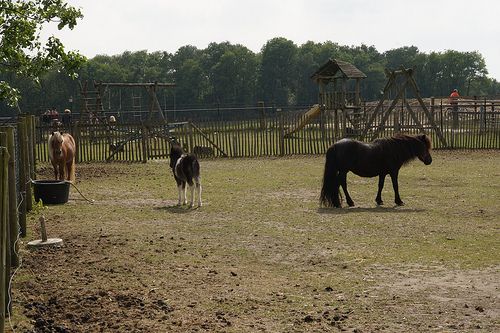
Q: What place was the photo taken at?
A: It was taken at the pasture.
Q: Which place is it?
A: It is a pasture.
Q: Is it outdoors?
A: Yes, it is outdoors.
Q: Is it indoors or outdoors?
A: It is outdoors.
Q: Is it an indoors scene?
A: No, it is outdoors.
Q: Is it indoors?
A: No, it is outdoors.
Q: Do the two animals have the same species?
A: Yes, all the animals are horses.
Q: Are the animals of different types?
A: No, all the animals are horses.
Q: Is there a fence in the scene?
A: Yes, there is a fence.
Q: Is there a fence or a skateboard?
A: Yes, there is a fence.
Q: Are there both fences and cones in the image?
A: No, there is a fence but no cones.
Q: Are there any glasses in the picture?
A: No, there are no glasses.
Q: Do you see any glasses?
A: No, there are no glasses.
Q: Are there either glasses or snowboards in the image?
A: No, there are no glasses or snowboards.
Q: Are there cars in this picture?
A: No, there are no cars.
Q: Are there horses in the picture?
A: Yes, there is a horse.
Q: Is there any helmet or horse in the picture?
A: Yes, there is a horse.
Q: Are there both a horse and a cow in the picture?
A: No, there is a horse but no cows.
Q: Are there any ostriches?
A: No, there are no ostriches.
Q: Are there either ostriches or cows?
A: No, there are no ostriches or cows.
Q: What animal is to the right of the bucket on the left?
A: The animal is a horse.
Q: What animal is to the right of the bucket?
A: The animal is a horse.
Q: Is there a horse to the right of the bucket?
A: Yes, there is a horse to the right of the bucket.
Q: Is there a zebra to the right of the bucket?
A: No, there is a horse to the right of the bucket.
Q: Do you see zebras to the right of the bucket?
A: No, there is a horse to the right of the bucket.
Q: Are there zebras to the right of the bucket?
A: No, there is a horse to the right of the bucket.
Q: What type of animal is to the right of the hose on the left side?
A: The animal is a horse.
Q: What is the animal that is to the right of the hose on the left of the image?
A: The animal is a horse.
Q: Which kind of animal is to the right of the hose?
A: The animal is a horse.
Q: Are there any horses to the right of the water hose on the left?
A: Yes, there is a horse to the right of the water hose.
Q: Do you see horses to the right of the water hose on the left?
A: Yes, there is a horse to the right of the water hose.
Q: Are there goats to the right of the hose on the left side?
A: No, there is a horse to the right of the water hose.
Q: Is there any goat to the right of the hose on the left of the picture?
A: No, there is a horse to the right of the water hose.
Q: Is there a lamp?
A: No, there are no lamps.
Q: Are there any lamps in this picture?
A: No, there are no lamps.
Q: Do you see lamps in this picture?
A: No, there are no lamps.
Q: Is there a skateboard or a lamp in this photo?
A: No, there are no lamps or skateboards.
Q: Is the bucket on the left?
A: Yes, the bucket is on the left of the image.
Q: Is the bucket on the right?
A: No, the bucket is on the left of the image.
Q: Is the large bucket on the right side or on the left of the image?
A: The bucket is on the left of the image.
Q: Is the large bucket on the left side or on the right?
A: The bucket is on the left of the image.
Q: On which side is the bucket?
A: The bucket is on the left of the image.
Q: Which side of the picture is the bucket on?
A: The bucket is on the left of the image.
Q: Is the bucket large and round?
A: Yes, the bucket is large and round.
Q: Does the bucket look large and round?
A: Yes, the bucket is large and round.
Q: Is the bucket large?
A: Yes, the bucket is large.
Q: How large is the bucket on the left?
A: The bucket is large.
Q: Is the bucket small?
A: No, the bucket is large.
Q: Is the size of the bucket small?
A: No, the bucket is large.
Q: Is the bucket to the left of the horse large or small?
A: The bucket is large.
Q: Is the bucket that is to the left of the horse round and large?
A: Yes, the bucket is round and large.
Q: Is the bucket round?
A: Yes, the bucket is round.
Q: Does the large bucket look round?
A: Yes, the bucket is round.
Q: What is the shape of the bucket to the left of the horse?
A: The bucket is round.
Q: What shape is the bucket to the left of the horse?
A: The bucket is round.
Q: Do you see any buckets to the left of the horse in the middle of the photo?
A: Yes, there is a bucket to the left of the horse.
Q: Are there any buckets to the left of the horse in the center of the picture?
A: Yes, there is a bucket to the left of the horse.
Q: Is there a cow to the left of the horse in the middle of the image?
A: No, there is a bucket to the left of the horse.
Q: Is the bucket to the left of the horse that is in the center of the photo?
A: Yes, the bucket is to the left of the horse.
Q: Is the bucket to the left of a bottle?
A: No, the bucket is to the left of the horse.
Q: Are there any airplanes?
A: No, there are no airplanes.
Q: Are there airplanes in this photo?
A: No, there are no airplanes.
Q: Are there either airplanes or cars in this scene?
A: No, there are no airplanes or cars.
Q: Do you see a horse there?
A: Yes, there is a horse.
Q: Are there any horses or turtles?
A: Yes, there is a horse.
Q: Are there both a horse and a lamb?
A: No, there is a horse but no lambs.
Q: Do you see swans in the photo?
A: No, there are no swans.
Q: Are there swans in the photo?
A: No, there are no swans.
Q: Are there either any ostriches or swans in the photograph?
A: No, there are no swans or ostriches.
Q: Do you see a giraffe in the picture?
A: No, there are no giraffes.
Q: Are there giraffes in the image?
A: No, there are no giraffes.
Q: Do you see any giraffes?
A: No, there are no giraffes.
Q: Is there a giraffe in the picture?
A: No, there are no giraffes.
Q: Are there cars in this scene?
A: No, there are no cars.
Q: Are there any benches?
A: No, there are no benches.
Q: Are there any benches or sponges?
A: No, there are no benches or sponges.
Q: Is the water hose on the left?
A: Yes, the water hose is on the left of the image.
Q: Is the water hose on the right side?
A: No, the water hose is on the left of the image.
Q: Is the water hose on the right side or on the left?
A: The water hose is on the left of the image.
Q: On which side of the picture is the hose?
A: The hose is on the left of the image.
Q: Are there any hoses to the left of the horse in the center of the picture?
A: Yes, there is a hose to the left of the horse.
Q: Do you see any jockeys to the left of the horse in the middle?
A: No, there is a hose to the left of the horse.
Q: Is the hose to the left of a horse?
A: Yes, the hose is to the left of a horse.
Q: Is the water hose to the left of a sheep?
A: No, the water hose is to the left of a horse.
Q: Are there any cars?
A: No, there are no cars.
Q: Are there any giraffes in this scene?
A: No, there are no giraffes.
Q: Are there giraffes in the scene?
A: No, there are no giraffes.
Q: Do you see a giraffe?
A: No, there are no giraffes.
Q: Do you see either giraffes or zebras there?
A: No, there are no giraffes or zebras.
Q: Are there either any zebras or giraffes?
A: No, there are no giraffes or zebras.